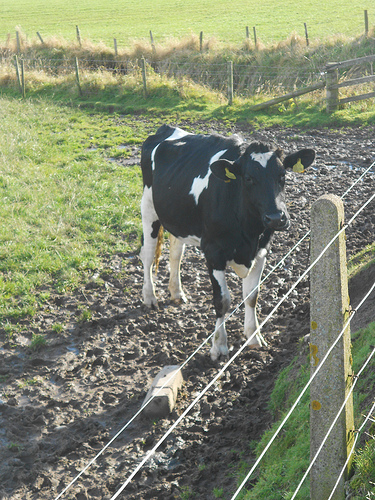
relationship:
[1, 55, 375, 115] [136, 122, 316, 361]
fence for cow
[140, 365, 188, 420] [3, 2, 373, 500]
plank of wood laying on ground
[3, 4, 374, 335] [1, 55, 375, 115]
grass near fence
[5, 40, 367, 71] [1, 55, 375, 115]
hay by fence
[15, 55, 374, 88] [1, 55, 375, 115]
wires sticking out of fence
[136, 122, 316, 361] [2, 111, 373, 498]
cow standing on mud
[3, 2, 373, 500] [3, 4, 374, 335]
ground has grass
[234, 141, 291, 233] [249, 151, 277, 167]
head has spot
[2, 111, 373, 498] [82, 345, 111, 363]
mud has step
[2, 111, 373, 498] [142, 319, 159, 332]
mud has step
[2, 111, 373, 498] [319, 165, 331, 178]
mud has step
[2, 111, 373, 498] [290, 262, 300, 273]
mud has step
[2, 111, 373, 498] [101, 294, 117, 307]
mud has step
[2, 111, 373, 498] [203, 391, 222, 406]
mud has step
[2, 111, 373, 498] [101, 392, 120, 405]
mud has step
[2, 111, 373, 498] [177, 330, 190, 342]
mud has step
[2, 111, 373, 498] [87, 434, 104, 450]
mud has step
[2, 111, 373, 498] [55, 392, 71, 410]
mud has step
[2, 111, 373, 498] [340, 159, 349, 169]
mud into step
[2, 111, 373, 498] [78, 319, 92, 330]
mud has step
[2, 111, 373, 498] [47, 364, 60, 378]
mud has step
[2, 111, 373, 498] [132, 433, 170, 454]
mud has step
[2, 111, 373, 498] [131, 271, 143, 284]
mud has step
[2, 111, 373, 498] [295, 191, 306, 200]
mud has step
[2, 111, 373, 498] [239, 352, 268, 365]
mud has step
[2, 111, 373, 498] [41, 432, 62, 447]
mud has step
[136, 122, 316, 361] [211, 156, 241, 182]
cow has ear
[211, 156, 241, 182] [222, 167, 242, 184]
ear has tag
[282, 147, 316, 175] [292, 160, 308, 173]
ear has tag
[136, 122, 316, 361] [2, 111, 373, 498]
cow standing in mud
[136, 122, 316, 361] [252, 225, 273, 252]
cow eating grass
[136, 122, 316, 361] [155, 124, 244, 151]
cow has back bone